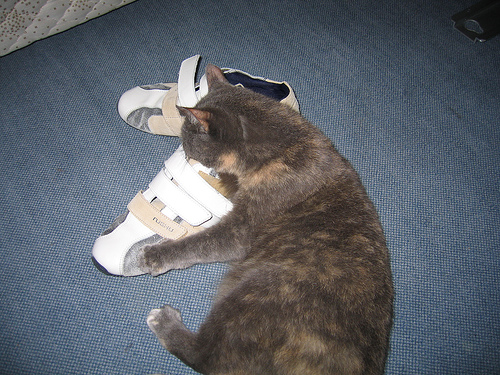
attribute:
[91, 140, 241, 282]
shoe — white, dark blue, grey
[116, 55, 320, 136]
shoe — dark blue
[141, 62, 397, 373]
cat — dark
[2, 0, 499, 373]
carpet — blue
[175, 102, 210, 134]
ear — cat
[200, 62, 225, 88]
ear — cat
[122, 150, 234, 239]
strap — white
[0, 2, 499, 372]
sofa cushion — blue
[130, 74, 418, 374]
cat — brown, grey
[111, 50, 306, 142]
shoe — white, grey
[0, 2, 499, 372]
surface — blue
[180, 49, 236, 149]
ears — pink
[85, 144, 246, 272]
shoe — white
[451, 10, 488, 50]
metal — hardware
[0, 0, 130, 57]
fabric — white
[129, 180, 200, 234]
strap — brown